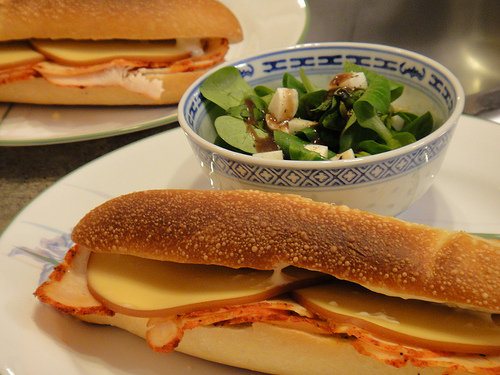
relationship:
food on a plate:
[47, 39, 499, 374] [1, 113, 495, 373]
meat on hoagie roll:
[30, 245, 497, 372] [72, 190, 499, 368]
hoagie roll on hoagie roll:
[3, 0, 249, 107] [3, 0, 249, 107]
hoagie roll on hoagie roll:
[3, 0, 249, 107] [72, 190, 499, 368]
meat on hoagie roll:
[0, 45, 228, 98] [72, 190, 499, 368]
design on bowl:
[247, 171, 402, 185] [183, 40, 455, 206]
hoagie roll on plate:
[72, 190, 499, 368] [1, 113, 495, 373]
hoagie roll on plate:
[72, 190, 499, 368] [25, 123, 474, 364]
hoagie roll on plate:
[3, 0, 249, 107] [0, 5, 289, 118]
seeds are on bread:
[234, 192, 288, 224] [70, 186, 499, 314]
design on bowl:
[383, 144, 415, 180] [176, 40, 481, 217]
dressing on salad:
[243, 99, 275, 154] [193, 56, 436, 161]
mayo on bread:
[262, 264, 291, 283] [130, 191, 481, 275]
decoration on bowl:
[208, 155, 408, 187] [176, 40, 481, 217]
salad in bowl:
[196, 58, 425, 168] [170, 24, 481, 267]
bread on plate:
[71, 191, 500, 275] [48, 72, 465, 370]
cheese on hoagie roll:
[83, 257, 309, 318] [72, 190, 499, 368]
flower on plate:
[257, 68, 332, 153] [24, 63, 361, 370]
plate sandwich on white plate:
[0, 0, 180, 147] [0, 113, 497, 373]